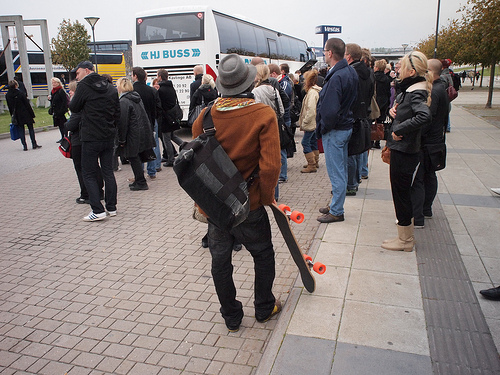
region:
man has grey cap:
[172, 36, 270, 109]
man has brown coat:
[194, 104, 281, 218]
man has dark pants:
[192, 212, 295, 369]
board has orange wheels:
[281, 194, 340, 286]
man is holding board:
[267, 179, 327, 304]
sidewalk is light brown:
[50, 205, 173, 360]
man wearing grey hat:
[205, 45, 280, 122]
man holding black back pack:
[160, 93, 283, 263]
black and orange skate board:
[271, 192, 338, 304]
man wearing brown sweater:
[167, 90, 297, 252]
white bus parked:
[124, 0, 338, 131]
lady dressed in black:
[378, 38, 437, 269]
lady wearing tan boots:
[371, 207, 421, 260]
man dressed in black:
[50, 55, 126, 243]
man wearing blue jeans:
[312, 115, 365, 228]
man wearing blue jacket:
[300, 53, 366, 143]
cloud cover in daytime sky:
[0, 1, 476, 50]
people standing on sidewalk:
[315, 35, 499, 252]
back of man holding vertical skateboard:
[178, 55, 322, 332]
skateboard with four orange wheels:
[270, 201, 327, 293]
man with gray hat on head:
[191, 52, 280, 332]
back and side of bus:
[133, 5, 312, 120]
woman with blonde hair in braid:
[383, 52, 435, 252]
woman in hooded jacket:
[119, 77, 154, 191]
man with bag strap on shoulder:
[172, 54, 281, 331]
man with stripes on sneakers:
[69, 62, 120, 222]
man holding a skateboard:
[187, 50, 327, 332]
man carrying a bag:
[165, 50, 325, 330]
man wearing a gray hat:
[175, 51, 325, 331]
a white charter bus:
[125, 5, 310, 127]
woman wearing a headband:
[380, 50, 432, 250]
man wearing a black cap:
[65, 60, 116, 220]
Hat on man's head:
[213, 50, 256, 97]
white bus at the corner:
[132, 2, 316, 122]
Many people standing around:
[11, 23, 455, 333]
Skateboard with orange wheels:
[270, 194, 326, 292]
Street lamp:
[86, 14, 101, 69]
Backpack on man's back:
[173, 94, 252, 229]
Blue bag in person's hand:
[6, 118, 22, 143]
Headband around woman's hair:
[406, 52, 418, 79]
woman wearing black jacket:
[381, 45, 432, 252]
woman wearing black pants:
[380, 43, 435, 249]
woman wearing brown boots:
[382, 46, 457, 272]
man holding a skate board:
[186, 57, 326, 320]